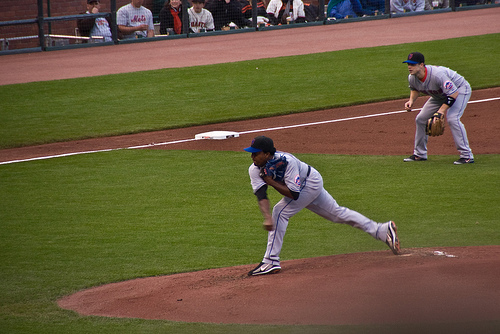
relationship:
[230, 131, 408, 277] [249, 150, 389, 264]
pitcher in uniform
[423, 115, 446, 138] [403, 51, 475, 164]
baseball glove on player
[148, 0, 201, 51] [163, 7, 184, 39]
woman witting with scarf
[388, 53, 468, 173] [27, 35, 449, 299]
baseball player on field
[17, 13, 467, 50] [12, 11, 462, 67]
dugout in stadium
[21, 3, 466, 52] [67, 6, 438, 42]
row of players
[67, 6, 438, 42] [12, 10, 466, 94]
players in dugout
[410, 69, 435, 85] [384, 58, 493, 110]
collar of shirt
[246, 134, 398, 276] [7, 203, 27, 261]
baseball player thrown ball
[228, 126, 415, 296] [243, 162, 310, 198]
baseball player in uniform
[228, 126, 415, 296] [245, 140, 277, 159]
baseball player in cap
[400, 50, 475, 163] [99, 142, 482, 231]
baseball player crouching in infield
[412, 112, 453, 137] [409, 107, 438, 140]
baseball glove on hand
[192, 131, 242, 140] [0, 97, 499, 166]
base sitting on foul line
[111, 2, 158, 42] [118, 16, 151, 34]
man wearing t-shirt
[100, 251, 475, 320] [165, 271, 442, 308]
pitcher's mound of dirt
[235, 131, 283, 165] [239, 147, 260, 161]
baseball cap with brim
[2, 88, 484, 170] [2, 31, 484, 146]
path in grass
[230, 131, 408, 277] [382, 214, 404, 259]
pitcher has shoe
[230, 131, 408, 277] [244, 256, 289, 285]
pitcher has shoe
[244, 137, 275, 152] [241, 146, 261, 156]
baseball cap with rim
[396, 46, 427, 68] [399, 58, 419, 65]
cap with rim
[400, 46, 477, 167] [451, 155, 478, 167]
player has foot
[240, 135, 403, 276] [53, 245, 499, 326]
pitcher has pitcher's mound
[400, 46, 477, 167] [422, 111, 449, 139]
player with glove